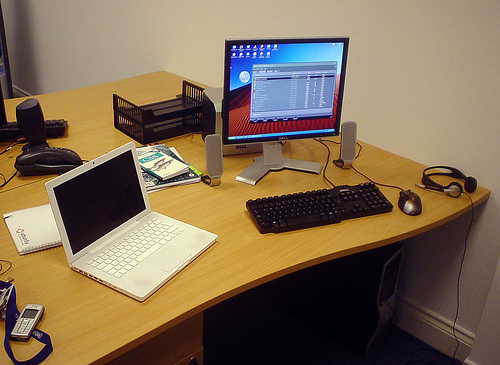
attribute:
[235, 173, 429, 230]
keyboard — black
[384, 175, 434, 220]
mouse — black, silver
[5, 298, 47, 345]
cellular phone — gray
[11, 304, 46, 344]
cell phone — silver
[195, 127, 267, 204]
speaker — Computer speaker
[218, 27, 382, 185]
monitor — computer monitor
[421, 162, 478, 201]
head set — silver and black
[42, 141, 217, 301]
laptop — white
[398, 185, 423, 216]
mouse — black, silver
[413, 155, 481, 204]
headphones — Black, silver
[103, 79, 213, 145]
tray — black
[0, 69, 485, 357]
desk — wood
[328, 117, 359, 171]
speaker — gray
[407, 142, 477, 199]
headset — black, gray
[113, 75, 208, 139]
holder — black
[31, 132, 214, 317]
laptop — White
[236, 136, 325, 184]
base — gray